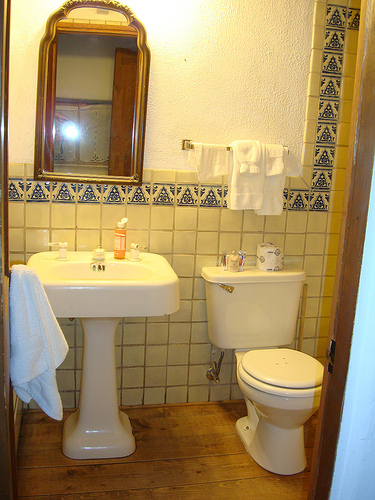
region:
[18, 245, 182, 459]
White pedestal bathroom sink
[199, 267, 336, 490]
White toilet with the lid down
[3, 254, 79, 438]
White towel hanging on doorknob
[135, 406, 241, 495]
Light brown wooden floor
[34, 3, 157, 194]
Gold framed mirror above the sink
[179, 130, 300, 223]
White towels hanging on a towel bar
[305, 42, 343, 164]
Decorative blue tiles arranged in a line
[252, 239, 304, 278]
Unwrapped toilet paper on back of toilet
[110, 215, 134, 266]
Orange and white bottle on sink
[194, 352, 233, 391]
Water hookup for toilet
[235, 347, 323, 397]
Closed lid of a white toilet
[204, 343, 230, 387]
Water intake hose of a toilet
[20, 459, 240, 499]
Wooden floor of a bathroom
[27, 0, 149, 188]
Mirror on the wall of a bathroom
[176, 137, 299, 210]
Towels hanging on a wall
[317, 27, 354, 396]
Yellow tiles on the end of a tile wall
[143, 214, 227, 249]
White tiles on the wall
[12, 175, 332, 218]
White tiles with blue triangles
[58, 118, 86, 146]
Reflection of flash bulb in a mirror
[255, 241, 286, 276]
Unopened roll of toilet paper on the tank of a toilet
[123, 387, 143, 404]
a tile on the wall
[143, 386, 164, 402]
a tile on the wall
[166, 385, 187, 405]
a tile on the wall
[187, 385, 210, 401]
a tile on the wall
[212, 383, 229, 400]
a tile on the wall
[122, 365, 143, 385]
a tile on the wall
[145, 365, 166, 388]
a tile on the wall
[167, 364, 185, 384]
a tile on the wall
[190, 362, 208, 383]
a tile on the wall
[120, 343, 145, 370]
a tile on the wall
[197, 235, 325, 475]
The toilet is white.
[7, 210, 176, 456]
The sink is white.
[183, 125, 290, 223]
White towels hanging on the rack.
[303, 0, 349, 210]
A row of blue and white tiles.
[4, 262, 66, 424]
A towel is hanging up.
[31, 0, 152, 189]
The mirror has gold trim around it.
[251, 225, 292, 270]
A roll of toilet paper.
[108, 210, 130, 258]
An open bottle on the sink.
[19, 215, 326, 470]
The sink and the toilet are white.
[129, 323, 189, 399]
Several white tiles.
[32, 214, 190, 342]
Bathroom sink and white towel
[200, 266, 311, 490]
White toilet in bathroom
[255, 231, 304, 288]
Roll of toilet paper on toilet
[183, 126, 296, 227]
White hand towels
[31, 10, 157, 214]
Bathroom mirror hanging on wall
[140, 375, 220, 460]
Hardwood floor and tiled wall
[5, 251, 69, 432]
Towel hanging from doorknob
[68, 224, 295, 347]
Bathroom sink and toilet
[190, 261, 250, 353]
Bathroom toilet and tiled wall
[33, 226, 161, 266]
Water faucet and hand soap